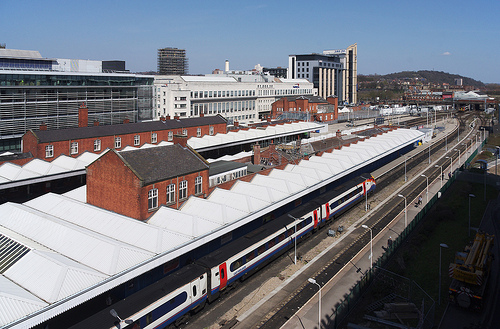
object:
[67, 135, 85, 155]
window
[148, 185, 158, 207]
window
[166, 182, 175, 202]
window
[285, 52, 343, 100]
building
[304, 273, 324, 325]
street light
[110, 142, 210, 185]
roof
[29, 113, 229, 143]
roof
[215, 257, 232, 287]
door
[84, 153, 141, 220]
wall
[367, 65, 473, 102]
mountain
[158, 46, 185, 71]
building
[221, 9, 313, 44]
sky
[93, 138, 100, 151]
window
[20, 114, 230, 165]
building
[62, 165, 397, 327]
train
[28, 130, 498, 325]
station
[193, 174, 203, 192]
window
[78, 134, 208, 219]
building